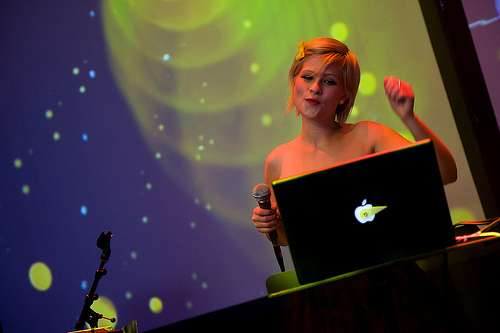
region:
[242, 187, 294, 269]
this is a microphone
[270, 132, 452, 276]
this is a laptop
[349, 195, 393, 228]
the laptop is of apple brand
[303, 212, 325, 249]
the laptop is black in color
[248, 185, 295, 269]
the microphone is small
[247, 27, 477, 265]
this is a woman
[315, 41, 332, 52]
the hair is blonde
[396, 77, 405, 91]
this is a ring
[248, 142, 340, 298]
the woman is holding the microphone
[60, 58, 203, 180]
the background is blue in color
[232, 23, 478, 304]
Young woman making a presentation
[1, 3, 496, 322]
Projected lights on the wall behind woman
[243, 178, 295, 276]
Microphone held by woman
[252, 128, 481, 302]
Laptop computer on the table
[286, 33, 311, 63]
Orange bow in woman's hair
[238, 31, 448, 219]
Pretty blonde woman with a microphone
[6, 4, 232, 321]
Blue backlit wall with yellow patterns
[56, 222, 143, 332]
vertical microphone stand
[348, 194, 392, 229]
Apple logo on the laptop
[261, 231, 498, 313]
Back desk with computer on top of it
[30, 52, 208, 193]
bubbles on a screen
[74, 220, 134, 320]
a black metal microphone stand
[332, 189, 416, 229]
a company logo on a computer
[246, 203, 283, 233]
a hand grasping a microphone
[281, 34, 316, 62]
a yellow bow in hair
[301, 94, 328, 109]
red lips on a face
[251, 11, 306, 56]
green light shining on a stage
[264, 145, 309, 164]
a bare shoulder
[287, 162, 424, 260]
a black laptop on a table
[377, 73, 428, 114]
a hand raised in the air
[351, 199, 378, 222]
Apple symbol on a laptop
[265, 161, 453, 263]
Black laptop in front of a woman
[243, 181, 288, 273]
Microphone in a woman's hand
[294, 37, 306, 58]
Yellow bow in a woman's hair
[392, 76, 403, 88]
Ring on a woman's finger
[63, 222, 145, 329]
Microphone stand next to a woman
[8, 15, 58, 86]
Blue wall behind a woman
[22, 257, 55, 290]
Yellow spot on a blue wall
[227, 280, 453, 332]
Brown table in front of a woman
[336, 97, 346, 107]
Earring in a woman's ear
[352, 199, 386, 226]
Branding logo behind a display unit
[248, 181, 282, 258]
Microphone held in the hand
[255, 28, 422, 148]
Woman looking into a display unit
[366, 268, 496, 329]
Black shade of color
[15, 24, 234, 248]
Multiple round spots on blue background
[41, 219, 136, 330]
Bare microphone stand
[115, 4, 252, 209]
Ripples of yellowish light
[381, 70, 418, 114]
Hand with a ring on a finger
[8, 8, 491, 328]
Woman performing before a glittering background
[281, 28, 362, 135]
Short har with a brooch on the side